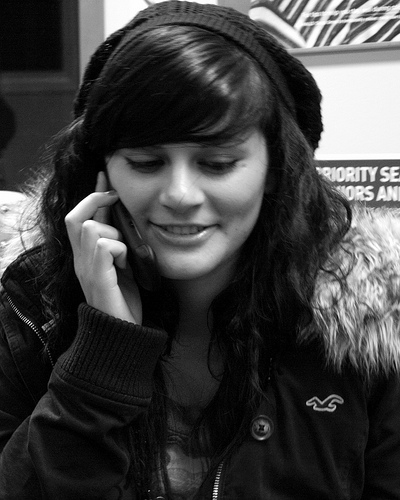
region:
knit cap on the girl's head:
[72, 1, 323, 144]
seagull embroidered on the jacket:
[306, 393, 341, 413]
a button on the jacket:
[250, 413, 273, 442]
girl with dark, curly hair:
[7, 5, 398, 497]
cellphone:
[103, 179, 159, 292]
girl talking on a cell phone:
[8, 7, 399, 499]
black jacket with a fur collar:
[4, 208, 396, 499]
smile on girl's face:
[146, 217, 219, 241]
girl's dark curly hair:
[41, 51, 351, 452]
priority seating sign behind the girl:
[317, 160, 399, 205]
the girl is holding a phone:
[64, 134, 230, 302]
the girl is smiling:
[146, 213, 214, 238]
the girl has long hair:
[45, 20, 329, 408]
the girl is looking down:
[89, 25, 270, 273]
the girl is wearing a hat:
[71, 4, 323, 160]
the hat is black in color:
[62, 7, 325, 149]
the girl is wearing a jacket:
[4, 234, 388, 496]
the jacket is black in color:
[3, 243, 391, 495]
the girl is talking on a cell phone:
[40, 23, 309, 335]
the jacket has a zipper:
[203, 453, 226, 499]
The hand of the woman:
[60, 167, 149, 332]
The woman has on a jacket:
[0, 202, 398, 493]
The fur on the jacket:
[331, 204, 399, 357]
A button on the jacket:
[244, 409, 277, 445]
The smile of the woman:
[131, 208, 244, 260]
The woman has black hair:
[35, 8, 372, 449]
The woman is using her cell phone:
[83, 164, 168, 300]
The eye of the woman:
[191, 140, 252, 188]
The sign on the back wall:
[313, 151, 399, 212]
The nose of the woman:
[153, 169, 211, 216]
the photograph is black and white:
[1, 1, 396, 498]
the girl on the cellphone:
[69, 14, 354, 435]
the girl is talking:
[36, 6, 370, 479]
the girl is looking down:
[56, 22, 346, 463]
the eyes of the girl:
[112, 154, 249, 176]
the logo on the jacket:
[303, 389, 344, 415]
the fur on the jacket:
[322, 210, 395, 362]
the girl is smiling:
[77, 29, 290, 282]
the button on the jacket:
[249, 409, 273, 445]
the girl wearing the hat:
[50, 3, 346, 330]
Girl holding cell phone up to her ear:
[31, 153, 170, 310]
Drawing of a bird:
[294, 384, 352, 418]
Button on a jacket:
[244, 407, 278, 444]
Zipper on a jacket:
[207, 452, 228, 490]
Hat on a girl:
[64, 0, 329, 142]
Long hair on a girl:
[260, 102, 360, 274]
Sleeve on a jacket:
[0, 299, 169, 498]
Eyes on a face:
[102, 139, 248, 188]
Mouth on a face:
[146, 212, 233, 245]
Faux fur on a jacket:
[312, 208, 398, 392]